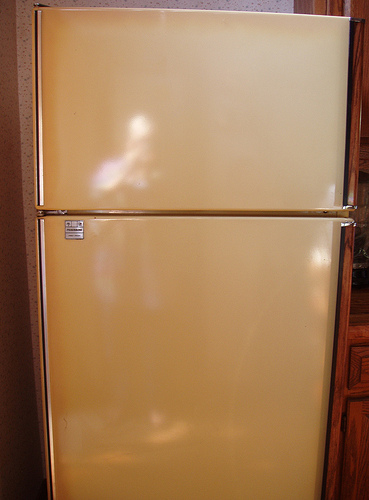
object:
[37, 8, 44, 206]
stripe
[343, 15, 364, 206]
handles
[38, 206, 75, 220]
hinge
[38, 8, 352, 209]
doors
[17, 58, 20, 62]
dots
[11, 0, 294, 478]
wall covering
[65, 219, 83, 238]
plate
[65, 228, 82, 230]
information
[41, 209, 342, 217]
space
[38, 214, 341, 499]
doors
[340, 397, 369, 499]
cabinets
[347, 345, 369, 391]
drawer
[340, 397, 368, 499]
door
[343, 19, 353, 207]
storage space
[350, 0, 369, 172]
cabinet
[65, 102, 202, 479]
reflection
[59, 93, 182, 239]
man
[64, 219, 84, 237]
magnet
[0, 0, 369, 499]
kitchen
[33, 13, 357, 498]
refrigerator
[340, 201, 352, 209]
hinges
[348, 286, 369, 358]
counter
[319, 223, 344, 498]
handle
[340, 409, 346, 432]
hinge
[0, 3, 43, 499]
wallpaper